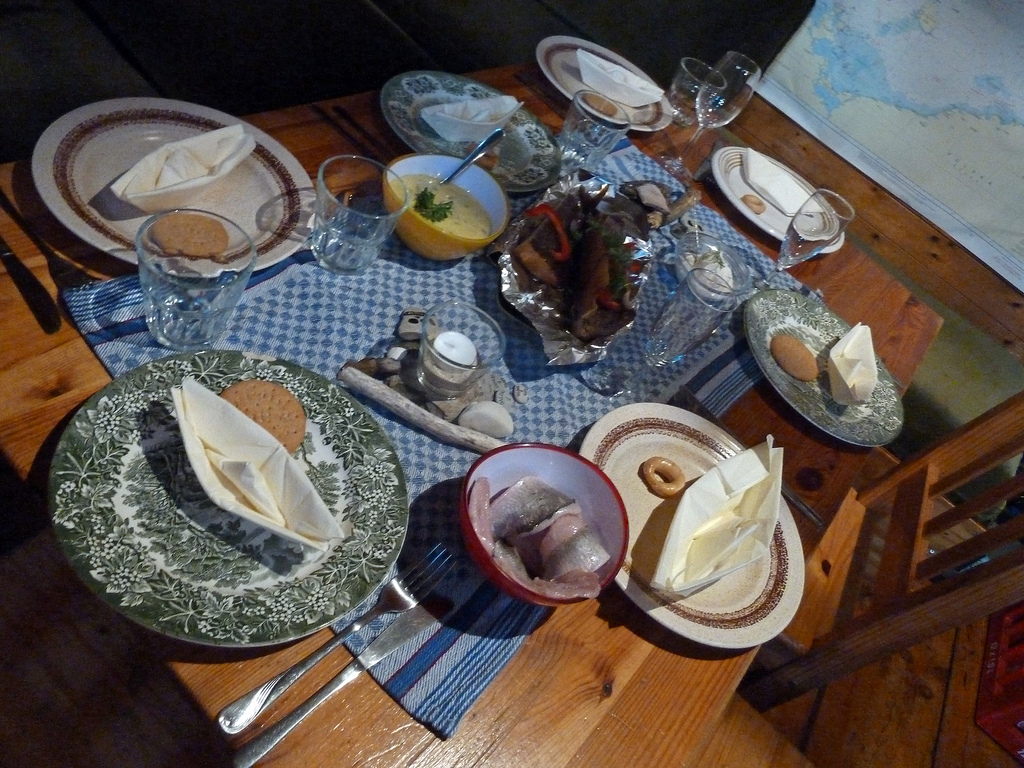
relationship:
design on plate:
[141, 522, 256, 609] [48, 330, 415, 669]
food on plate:
[542, 405, 793, 641] [600, 410, 806, 645]